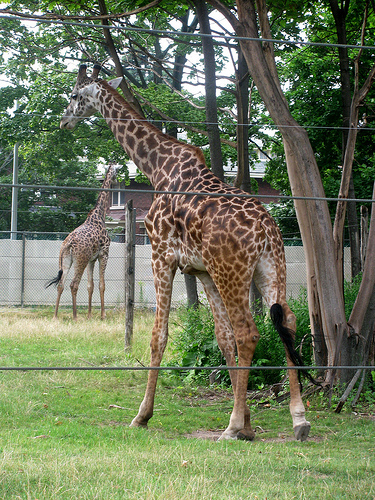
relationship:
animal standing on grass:
[43, 163, 123, 320] [22, 458, 103, 496]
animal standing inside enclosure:
[43, 163, 123, 320] [4, 12, 372, 373]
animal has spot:
[40, 47, 360, 482] [227, 219, 237, 232]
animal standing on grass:
[43, 163, 123, 320] [62, 443, 115, 479]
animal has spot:
[59, 62, 325, 442] [172, 207, 189, 218]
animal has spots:
[67, 62, 313, 443] [99, 85, 300, 359]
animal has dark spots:
[67, 62, 313, 443] [161, 205, 232, 236]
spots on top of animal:
[197, 200, 224, 218] [67, 62, 313, 443]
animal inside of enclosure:
[43, 163, 123, 320] [27, 109, 272, 306]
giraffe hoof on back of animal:
[294, 424, 311, 440] [43, 163, 123, 320]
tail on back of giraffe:
[262, 213, 325, 390] [57, 61, 322, 443]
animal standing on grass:
[43, 163, 123, 320] [6, 451, 370, 494]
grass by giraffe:
[0, 308, 374, 498] [44, 162, 117, 320]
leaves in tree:
[294, 55, 338, 97] [239, 60, 329, 173]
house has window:
[23, 157, 286, 233] [105, 183, 125, 219]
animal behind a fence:
[43, 163, 123, 320] [0, 230, 303, 307]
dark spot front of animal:
[207, 226, 225, 247] [67, 62, 313, 443]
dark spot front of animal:
[212, 203, 237, 218] [67, 62, 313, 443]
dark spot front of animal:
[193, 160, 206, 173] [67, 62, 313, 443]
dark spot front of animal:
[152, 138, 174, 157] [67, 62, 313, 443]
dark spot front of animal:
[199, 170, 214, 182] [67, 62, 313, 443]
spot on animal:
[226, 273, 233, 283] [67, 62, 313, 443]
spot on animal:
[235, 279, 243, 287] [67, 62, 313, 443]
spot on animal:
[226, 283, 231, 289] [67, 62, 313, 443]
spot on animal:
[221, 276, 228, 285] [67, 62, 313, 443]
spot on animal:
[233, 275, 240, 283] [67, 62, 313, 443]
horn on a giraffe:
[90, 62, 100, 77] [57, 61, 322, 443]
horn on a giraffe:
[76, 61, 86, 81] [57, 61, 322, 443]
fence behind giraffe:
[0, 230, 303, 307] [57, 61, 322, 443]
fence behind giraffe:
[0, 230, 303, 307] [44, 162, 117, 320]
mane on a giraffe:
[98, 79, 205, 162] [57, 61, 322, 443]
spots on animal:
[157, 282, 168, 329] [67, 62, 313, 443]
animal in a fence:
[43, 163, 123, 320] [0, 230, 303, 307]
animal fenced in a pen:
[59, 62, 325, 442] [1, 12, 372, 372]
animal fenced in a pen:
[43, 163, 123, 320] [1, 12, 372, 372]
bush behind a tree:
[167, 295, 318, 398] [205, 0, 371, 384]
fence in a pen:
[0, 217, 162, 316] [5, 161, 374, 365]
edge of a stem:
[208, 1, 325, 377] [204, 0, 373, 382]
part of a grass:
[172, 421, 221, 466] [0, 308, 374, 498]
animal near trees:
[59, 62, 325, 442] [2, 2, 367, 332]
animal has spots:
[67, 62, 313, 443] [196, 202, 217, 215]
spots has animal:
[98, 204, 103, 211] [42, 163, 122, 317]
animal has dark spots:
[67, 62, 313, 443] [181, 186, 191, 208]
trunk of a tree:
[283, 137, 372, 389] [244, 74, 326, 229]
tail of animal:
[256, 213, 332, 391] [43, 163, 123, 320]